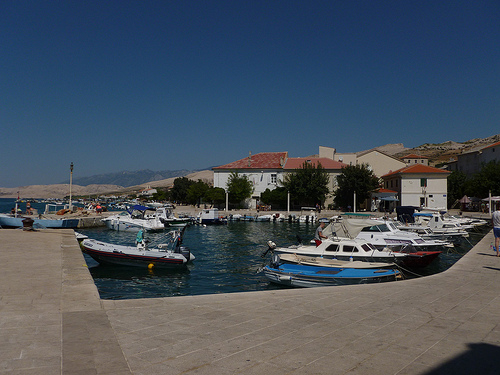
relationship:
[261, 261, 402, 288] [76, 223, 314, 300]
blue boat in deep blue water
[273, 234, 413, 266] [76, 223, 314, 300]
boat in deep blue water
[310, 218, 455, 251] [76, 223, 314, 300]
boat in deep blue water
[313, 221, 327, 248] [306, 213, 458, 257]
guy in boat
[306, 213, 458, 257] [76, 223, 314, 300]
boat in deep blue water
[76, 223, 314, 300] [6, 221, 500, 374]
deep blue water surrounding tile deck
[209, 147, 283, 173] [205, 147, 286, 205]
roof on building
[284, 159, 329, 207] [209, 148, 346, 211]
tree near building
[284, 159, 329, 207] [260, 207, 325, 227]
tree behind boat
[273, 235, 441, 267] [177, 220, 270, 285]
boat parked by water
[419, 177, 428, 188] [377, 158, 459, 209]
window on building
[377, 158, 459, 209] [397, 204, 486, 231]
building behind boat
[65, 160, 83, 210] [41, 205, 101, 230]
post behind boat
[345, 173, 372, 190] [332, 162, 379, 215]
leaves are on tree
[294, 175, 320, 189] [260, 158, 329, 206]
leaves are on tree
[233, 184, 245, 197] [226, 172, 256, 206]
leaves are on tree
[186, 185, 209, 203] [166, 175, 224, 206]
leaves are on tree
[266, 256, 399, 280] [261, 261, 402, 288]
top on blue boat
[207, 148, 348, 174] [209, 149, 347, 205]
roof on building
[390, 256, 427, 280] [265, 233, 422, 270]
rope on boat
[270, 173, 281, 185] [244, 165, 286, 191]
window on wall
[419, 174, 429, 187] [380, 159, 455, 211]
window on building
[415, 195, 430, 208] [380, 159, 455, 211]
window on building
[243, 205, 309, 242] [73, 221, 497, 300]
reflection on water on water surface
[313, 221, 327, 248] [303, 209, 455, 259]
guy on boat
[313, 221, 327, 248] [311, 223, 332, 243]
guy wearing gray shirt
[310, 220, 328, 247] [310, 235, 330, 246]
guy wearing red shorts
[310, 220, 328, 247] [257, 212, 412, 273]
guy on boat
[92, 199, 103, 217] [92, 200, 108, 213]
person wearing pink shirt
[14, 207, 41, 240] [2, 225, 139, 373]
black trash on platform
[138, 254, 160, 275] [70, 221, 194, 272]
yellow ball on side of boat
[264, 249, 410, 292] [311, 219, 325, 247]
blue boat next to man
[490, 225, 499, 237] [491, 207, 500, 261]
shorts on man on the right